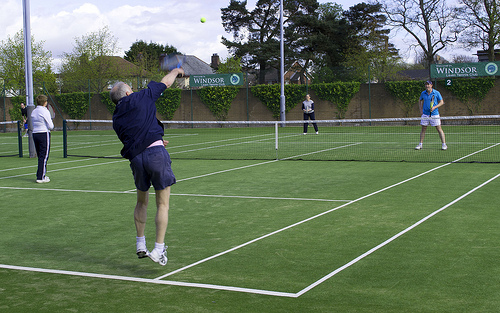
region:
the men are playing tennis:
[2, 67, 471, 259]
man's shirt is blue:
[100, 81, 197, 169]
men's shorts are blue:
[118, 142, 192, 197]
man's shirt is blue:
[417, 88, 447, 116]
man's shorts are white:
[413, 109, 448, 132]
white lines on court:
[3, 123, 498, 298]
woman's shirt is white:
[20, 101, 65, 136]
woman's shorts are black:
[28, 120, 55, 180]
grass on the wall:
[13, 73, 494, 115]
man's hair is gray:
[98, 67, 150, 104]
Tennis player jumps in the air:
[95, 14, 202, 311]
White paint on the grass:
[295, 206, 423, 306]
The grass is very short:
[370, 271, 402, 305]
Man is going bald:
[104, 70, 139, 107]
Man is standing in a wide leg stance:
[388, 75, 482, 171]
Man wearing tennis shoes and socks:
[131, 228, 176, 275]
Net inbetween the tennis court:
[187, 96, 429, 206]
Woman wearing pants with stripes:
[22, 124, 54, 188]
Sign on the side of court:
[162, 41, 254, 99]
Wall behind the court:
[220, 72, 452, 169]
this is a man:
[94, 104, 229, 277]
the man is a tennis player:
[116, 139, 158, 194]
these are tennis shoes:
[129, 211, 192, 281]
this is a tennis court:
[295, 178, 387, 310]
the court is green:
[221, 241, 292, 308]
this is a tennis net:
[244, 90, 333, 175]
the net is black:
[255, 105, 306, 167]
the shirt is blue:
[99, 94, 156, 156]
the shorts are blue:
[81, 102, 149, 183]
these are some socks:
[93, 187, 184, 272]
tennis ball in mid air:
[192, 13, 213, 30]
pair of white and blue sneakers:
[122, 239, 172, 269]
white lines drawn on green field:
[150, 195, 367, 310]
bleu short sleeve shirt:
[408, 89, 450, 114]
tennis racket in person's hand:
[425, 93, 437, 122]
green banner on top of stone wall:
[420, 55, 498, 83]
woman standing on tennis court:
[17, 89, 67, 189]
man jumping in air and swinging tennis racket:
[98, 41, 219, 272]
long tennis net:
[55, 107, 496, 178]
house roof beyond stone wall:
[150, 42, 222, 75]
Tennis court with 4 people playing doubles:
[7, 75, 498, 301]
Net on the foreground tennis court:
[59, 112, 498, 174]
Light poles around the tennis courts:
[18, 5, 313, 132]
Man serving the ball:
[107, 57, 237, 294]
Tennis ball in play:
[188, 3, 220, 35]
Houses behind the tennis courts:
[50, 51, 319, 86]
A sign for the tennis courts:
[187, 72, 243, 91]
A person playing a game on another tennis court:
[13, 103, 29, 129]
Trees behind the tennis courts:
[228, 7, 498, 72]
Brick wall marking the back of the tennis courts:
[6, 72, 499, 129]